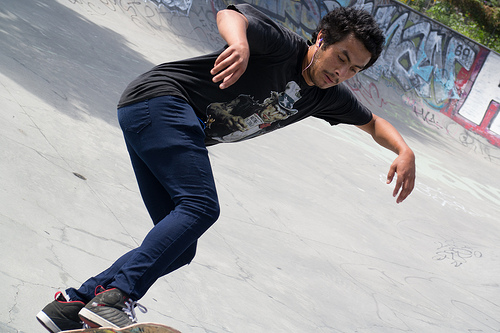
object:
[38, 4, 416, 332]
man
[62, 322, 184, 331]
skateboard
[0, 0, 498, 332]
pavement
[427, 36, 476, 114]
graffiti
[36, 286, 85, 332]
foot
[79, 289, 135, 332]
shoe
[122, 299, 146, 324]
laces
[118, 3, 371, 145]
shirt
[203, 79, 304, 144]
picture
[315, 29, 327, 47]
ear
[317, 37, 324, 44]
earbud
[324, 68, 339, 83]
mustache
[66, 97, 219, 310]
jeans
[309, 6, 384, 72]
hair